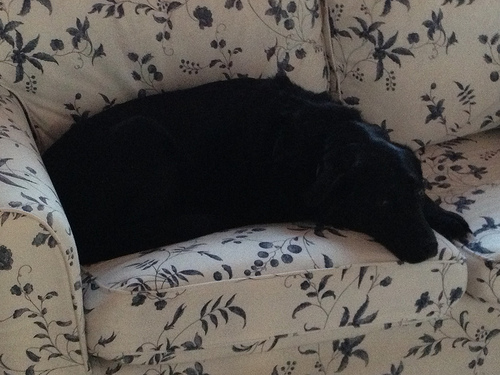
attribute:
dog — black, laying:
[81, 74, 426, 237]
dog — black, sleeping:
[56, 60, 455, 253]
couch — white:
[113, 240, 485, 368]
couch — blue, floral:
[125, 234, 435, 364]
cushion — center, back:
[325, 10, 493, 128]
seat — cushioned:
[94, 230, 410, 341]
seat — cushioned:
[415, 140, 496, 218]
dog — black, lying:
[66, 95, 356, 235]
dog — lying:
[99, 92, 431, 237]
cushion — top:
[126, 229, 387, 344]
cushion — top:
[355, 16, 491, 146]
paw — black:
[424, 201, 485, 252]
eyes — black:
[368, 178, 441, 208]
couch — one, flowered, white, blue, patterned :
[16, 12, 491, 373]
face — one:
[375, 181, 441, 266]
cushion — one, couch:
[96, 220, 473, 357]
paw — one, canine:
[428, 205, 477, 247]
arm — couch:
[6, 84, 80, 371]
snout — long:
[410, 226, 447, 266]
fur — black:
[86, 122, 195, 181]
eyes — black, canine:
[366, 187, 436, 217]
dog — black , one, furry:
[50, 78, 464, 262]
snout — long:
[386, 212, 445, 258]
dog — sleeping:
[37, 70, 474, 270]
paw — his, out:
[433, 202, 473, 246]